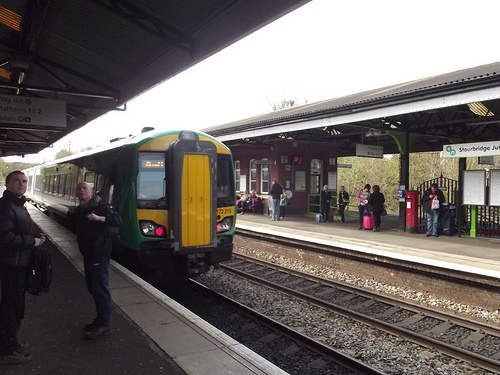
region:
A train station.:
[6, 102, 497, 359]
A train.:
[10, 121, 240, 290]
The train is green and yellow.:
[6, 120, 252, 286]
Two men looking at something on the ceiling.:
[3, 161, 122, 361]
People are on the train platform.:
[236, 170, 490, 250]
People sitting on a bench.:
[235, 185, 269, 218]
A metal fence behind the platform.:
[408, 171, 498, 234]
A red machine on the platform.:
[403, 178, 423, 236]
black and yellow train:
[81, 130, 247, 272]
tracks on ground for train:
[186, 260, 406, 365]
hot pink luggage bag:
[363, 215, 377, 235]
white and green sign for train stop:
[431, 137, 495, 168]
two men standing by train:
[0, 173, 122, 330]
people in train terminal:
[256, 160, 405, 242]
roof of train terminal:
[244, 109, 434, 137]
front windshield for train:
[136, 142, 249, 221]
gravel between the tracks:
[281, 301, 355, 353]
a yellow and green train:
[45, 128, 236, 283]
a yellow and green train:
[19, 161, 41, 204]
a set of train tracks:
[149, 274, 376, 374]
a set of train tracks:
[221, 251, 498, 368]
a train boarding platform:
[0, 200, 283, 374]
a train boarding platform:
[234, 208, 498, 275]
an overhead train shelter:
[0, 0, 311, 158]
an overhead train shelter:
[191, 59, 498, 153]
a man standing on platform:
[63, 181, 113, 345]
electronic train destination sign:
[138, 155, 164, 170]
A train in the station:
[107, 124, 249, 281]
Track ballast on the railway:
[267, 279, 389, 368]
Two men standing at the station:
[2, 161, 133, 349]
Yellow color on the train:
[178, 139, 218, 247]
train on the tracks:
[27, 118, 266, 313]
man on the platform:
[45, 157, 138, 345]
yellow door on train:
[167, 140, 232, 251]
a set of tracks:
[197, 234, 482, 370]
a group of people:
[244, 161, 456, 258]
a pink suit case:
[354, 200, 382, 237]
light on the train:
[139, 221, 161, 239]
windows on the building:
[231, 150, 271, 197]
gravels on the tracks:
[235, 245, 497, 373]